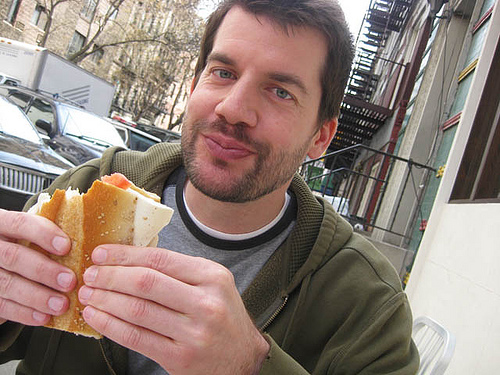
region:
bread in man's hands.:
[87, 211, 137, 228]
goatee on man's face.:
[217, 180, 255, 199]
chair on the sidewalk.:
[412, 312, 440, 372]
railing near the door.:
[382, 164, 418, 211]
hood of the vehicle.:
[10, 145, 50, 162]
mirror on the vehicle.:
[33, 120, 53, 137]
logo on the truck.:
[60, 82, 94, 99]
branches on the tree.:
[142, 23, 195, 52]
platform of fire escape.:
[350, 105, 377, 130]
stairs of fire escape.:
[369, 24, 377, 59]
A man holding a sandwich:
[0, 0, 420, 372]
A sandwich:
[24, 173, 175, 341]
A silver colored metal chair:
[408, 313, 455, 373]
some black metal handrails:
[293, 143, 436, 247]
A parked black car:
[0, 97, 75, 217]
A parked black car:
[1, 77, 131, 168]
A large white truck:
[0, 37, 114, 117]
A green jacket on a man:
[0, 139, 422, 374]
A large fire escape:
[321, 0, 419, 171]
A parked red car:
[115, 110, 135, 126]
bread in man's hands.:
[105, 205, 139, 222]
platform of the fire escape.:
[341, 105, 387, 127]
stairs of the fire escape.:
[365, 25, 375, 57]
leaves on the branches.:
[161, 29, 183, 57]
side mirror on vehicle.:
[37, 119, 52, 132]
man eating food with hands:
[28, 3, 385, 353]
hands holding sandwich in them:
[0, 148, 242, 342]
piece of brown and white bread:
[35, 163, 173, 267]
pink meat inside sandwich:
[85, 168, 136, 199]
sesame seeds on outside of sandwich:
[66, 200, 128, 278]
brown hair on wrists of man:
[210, 331, 277, 373]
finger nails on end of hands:
[12, 223, 79, 312]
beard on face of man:
[135, 110, 344, 222]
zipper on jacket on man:
[245, 291, 297, 343]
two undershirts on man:
[164, 208, 303, 254]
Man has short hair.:
[283, 16, 386, 111]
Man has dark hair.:
[290, 14, 393, 112]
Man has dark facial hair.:
[180, 112, 324, 236]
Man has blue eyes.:
[208, 65, 309, 129]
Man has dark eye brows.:
[197, 42, 324, 107]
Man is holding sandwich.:
[26, 179, 211, 354]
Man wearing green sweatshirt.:
[296, 249, 373, 361]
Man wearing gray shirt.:
[202, 244, 253, 291]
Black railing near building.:
[342, 145, 419, 242]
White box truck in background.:
[9, 48, 86, 88]